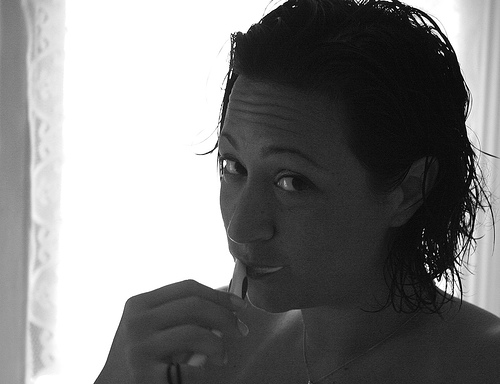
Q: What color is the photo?
A: Black and white.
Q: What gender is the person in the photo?
A: Female.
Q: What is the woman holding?
A: Toothbrush.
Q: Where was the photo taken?
A: Probably Bathroom.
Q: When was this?
A: Daytime.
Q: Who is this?
A: A woman.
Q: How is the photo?
A: Clear.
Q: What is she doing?
A: Brushing her teeth.